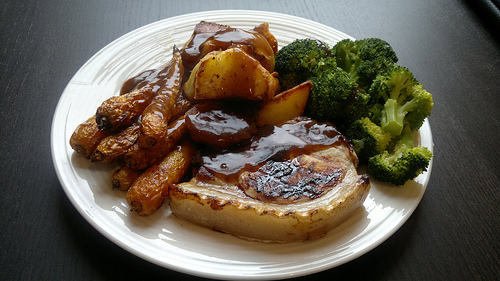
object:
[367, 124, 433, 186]
broccoli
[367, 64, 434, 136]
broccoli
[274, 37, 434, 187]
broccoli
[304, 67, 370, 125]
broccoli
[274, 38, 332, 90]
broccoli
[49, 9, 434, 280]
plate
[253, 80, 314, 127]
white potato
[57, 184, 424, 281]
shade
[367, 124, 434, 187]
vege